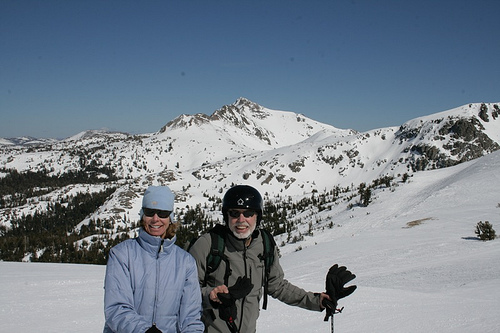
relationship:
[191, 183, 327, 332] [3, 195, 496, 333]
man on slope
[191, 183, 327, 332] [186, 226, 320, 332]
man in jacket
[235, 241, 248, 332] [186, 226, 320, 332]
zipper on jacket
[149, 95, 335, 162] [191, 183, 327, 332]
mountain behind man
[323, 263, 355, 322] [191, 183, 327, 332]
glove on man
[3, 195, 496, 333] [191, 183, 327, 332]
slope by man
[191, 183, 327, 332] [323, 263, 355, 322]
man has glove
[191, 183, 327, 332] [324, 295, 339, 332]
man has pole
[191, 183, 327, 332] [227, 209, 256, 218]
man with glasses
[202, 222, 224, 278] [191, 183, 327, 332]
strap on man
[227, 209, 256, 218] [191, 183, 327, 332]
glasses on man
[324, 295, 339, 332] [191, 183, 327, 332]
pole with man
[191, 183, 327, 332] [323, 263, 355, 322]
man with glove